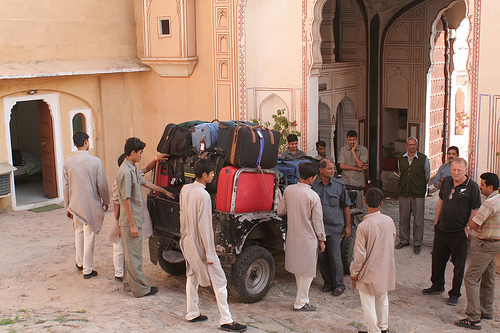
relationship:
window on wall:
[155, 15, 174, 40] [1, 0, 311, 214]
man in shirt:
[281, 157, 331, 309] [287, 185, 324, 265]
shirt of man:
[262, 190, 341, 267] [275, 162, 326, 311]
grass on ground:
[0, 307, 87, 329] [0, 192, 497, 331]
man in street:
[421, 157, 481, 306] [4, 181, 496, 329]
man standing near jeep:
[349, 187, 398, 333] [144, 120, 363, 301]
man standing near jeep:
[275, 162, 326, 311] [144, 120, 363, 301]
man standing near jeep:
[178, 158, 248, 333] [144, 120, 363, 301]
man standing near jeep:
[115, 137, 176, 299] [144, 120, 363, 301]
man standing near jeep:
[60, 131, 109, 280] [144, 120, 363, 301]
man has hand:
[337, 128, 371, 225] [348, 138, 360, 150]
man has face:
[337, 128, 371, 225] [346, 135, 357, 147]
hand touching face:
[348, 138, 360, 150] [346, 135, 357, 147]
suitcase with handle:
[217, 122, 281, 172] [249, 123, 262, 128]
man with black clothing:
[421, 157, 481, 306] [421, 174, 483, 305]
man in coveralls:
[115, 137, 176, 299] [114, 161, 144, 288]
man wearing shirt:
[454, 172, 500, 331] [468, 188, 499, 239]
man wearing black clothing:
[416, 155, 478, 309] [437, 174, 482, 233]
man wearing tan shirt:
[60, 131, 109, 280] [61, 150, 108, 235]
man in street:
[349, 187, 398, 333] [5, 260, 82, 326]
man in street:
[454, 172, 500, 331] [4, 181, 496, 329]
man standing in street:
[368, 131, 472, 233] [2, 211, 498, 329]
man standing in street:
[339, 132, 406, 331] [2, 211, 498, 329]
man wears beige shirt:
[349, 187, 398, 333] [360, 218, 405, 286]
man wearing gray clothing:
[310, 158, 351, 297] [303, 177, 357, 292]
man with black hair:
[178, 156, 246, 332] [192, 159, 213, 177]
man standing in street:
[178, 158, 248, 333] [2, 211, 498, 329]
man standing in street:
[115, 137, 176, 299] [2, 211, 498, 329]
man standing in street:
[60, 131, 109, 280] [2, 211, 498, 329]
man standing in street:
[275, 162, 326, 311] [2, 211, 498, 329]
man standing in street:
[349, 187, 398, 333] [2, 211, 498, 329]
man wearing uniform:
[314, 157, 351, 297] [316, 174, 354, 285]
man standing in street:
[178, 156, 246, 332] [4, 181, 496, 329]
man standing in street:
[60, 129, 109, 278] [4, 181, 496, 329]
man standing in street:
[349, 187, 398, 333] [4, 181, 496, 329]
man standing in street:
[465, 171, 499, 331] [4, 181, 496, 329]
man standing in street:
[115, 134, 175, 299] [4, 181, 496, 329]